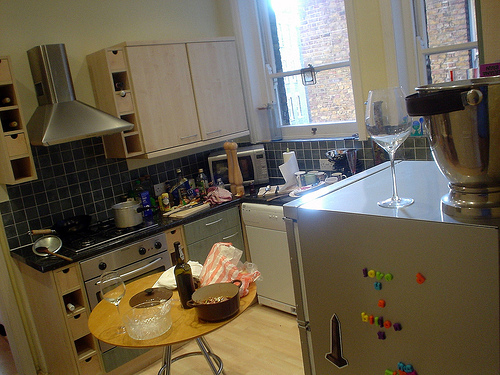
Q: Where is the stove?
A: On the left.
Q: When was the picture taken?
A: Daytime.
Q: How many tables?
A: One.